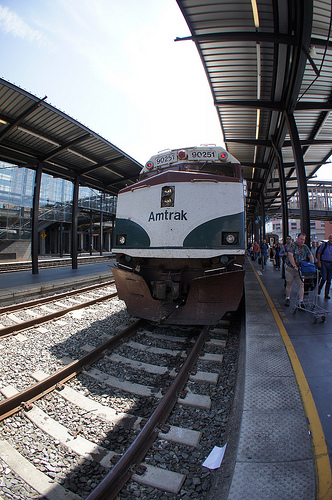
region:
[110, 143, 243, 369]
a train is on the tracks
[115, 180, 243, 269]
the headlights are on front of the train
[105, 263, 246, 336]
the front of the train has a cow pusher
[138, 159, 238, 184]
windshield wipers are on the engine's windows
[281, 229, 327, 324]
a man is pushing a luggage cart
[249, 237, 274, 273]
passengers are carrying bags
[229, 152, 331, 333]
people are on the platform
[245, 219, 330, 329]
passengers are disembarking from the train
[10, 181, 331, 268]
an overpass is behind the train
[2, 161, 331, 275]
buildings are around the terminal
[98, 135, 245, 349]
train on the track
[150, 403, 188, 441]
metal beam of track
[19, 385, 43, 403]
metal beam of track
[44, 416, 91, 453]
crosstie of train track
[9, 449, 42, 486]
crosstie of train track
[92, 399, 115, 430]
crosstie of train track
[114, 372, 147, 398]
crosstie of train track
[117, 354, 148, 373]
crosstie of train track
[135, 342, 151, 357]
crosstie of train track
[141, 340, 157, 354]
crosstie of train track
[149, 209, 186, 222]
the word amtrak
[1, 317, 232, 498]
a rusty pair of train tracks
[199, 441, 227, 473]
a white piece of paper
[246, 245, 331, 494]
a platform at a trainstation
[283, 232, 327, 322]
a man pushing a bag cart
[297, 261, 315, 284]
a blue shoulder bag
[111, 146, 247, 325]
the front of a train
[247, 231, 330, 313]
a group of people on a train platform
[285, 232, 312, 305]
a man in short pants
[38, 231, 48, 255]
a yellow sign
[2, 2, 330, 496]
the train is disembarking passengers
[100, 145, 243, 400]
a train is on the tracks at a terminal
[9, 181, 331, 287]
an overpass is above the train and tracks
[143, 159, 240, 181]
the engine windows have windshield wpiers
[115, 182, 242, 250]
the headlights are on the front of the train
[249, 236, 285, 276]
passengers are carrying luggage on the platform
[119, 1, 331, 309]
the terminal's overhang is above the train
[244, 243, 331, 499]
a yellow line is along the edge of the platform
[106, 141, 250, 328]
train stopped on tracks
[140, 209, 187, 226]
Amtrak written on front of train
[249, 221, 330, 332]
people waiting on train platform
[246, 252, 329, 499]
yellow line painted on train platform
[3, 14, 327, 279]
shelters over train platforms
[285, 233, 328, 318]
man pushing cart along platform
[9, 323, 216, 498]
tracks in front of train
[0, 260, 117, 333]
unused tracks beside train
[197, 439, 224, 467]
white paper on gravel around train tracks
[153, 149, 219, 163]
black numbers on front of train